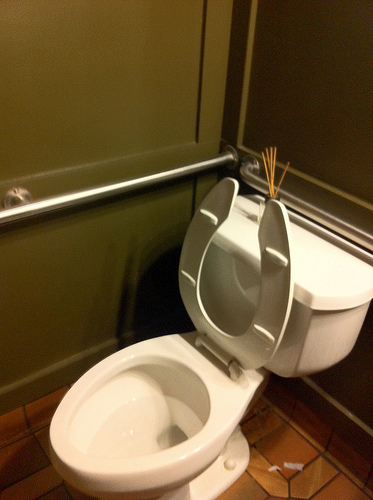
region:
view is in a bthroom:
[86, 204, 352, 490]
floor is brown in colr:
[269, 417, 334, 498]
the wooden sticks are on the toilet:
[249, 146, 294, 211]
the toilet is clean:
[102, 337, 284, 476]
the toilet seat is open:
[107, 256, 245, 478]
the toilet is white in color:
[107, 268, 250, 499]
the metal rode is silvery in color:
[50, 154, 210, 206]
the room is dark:
[53, 95, 322, 377]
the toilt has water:
[125, 392, 223, 452]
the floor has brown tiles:
[270, 431, 330, 494]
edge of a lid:
[267, 308, 295, 355]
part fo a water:
[169, 431, 176, 440]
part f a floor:
[272, 420, 302, 448]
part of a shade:
[148, 370, 163, 387]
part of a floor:
[267, 418, 301, 459]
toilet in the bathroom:
[41, 115, 279, 494]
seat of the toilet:
[171, 205, 290, 364]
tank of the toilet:
[286, 214, 354, 279]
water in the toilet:
[130, 405, 172, 445]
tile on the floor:
[272, 433, 322, 491]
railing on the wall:
[39, 171, 139, 230]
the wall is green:
[289, 47, 349, 141]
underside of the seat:
[233, 342, 276, 357]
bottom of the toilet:
[215, 458, 245, 488]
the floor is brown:
[236, 440, 332, 490]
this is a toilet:
[40, 174, 367, 495]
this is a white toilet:
[43, 172, 367, 498]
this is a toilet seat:
[178, 176, 299, 373]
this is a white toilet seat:
[179, 176, 286, 367]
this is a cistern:
[177, 176, 372, 377]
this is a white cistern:
[178, 175, 371, 379]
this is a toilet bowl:
[42, 336, 240, 499]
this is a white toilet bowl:
[46, 330, 263, 498]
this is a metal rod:
[3, 191, 43, 228]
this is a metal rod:
[150, 142, 237, 167]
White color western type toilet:
[38, 168, 360, 498]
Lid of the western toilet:
[173, 182, 291, 382]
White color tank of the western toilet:
[297, 239, 357, 372]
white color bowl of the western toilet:
[41, 448, 160, 490]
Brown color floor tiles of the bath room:
[270, 430, 312, 490]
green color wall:
[8, 10, 134, 84]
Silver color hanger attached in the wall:
[6, 141, 246, 212]